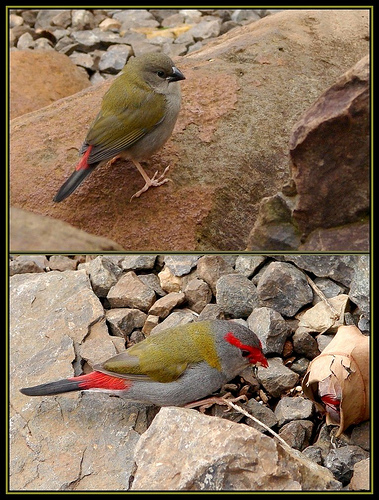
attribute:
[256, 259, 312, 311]
rocks — brown, gray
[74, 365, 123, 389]
feathers — red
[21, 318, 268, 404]
bird — green, feathered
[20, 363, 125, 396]
tail — bird's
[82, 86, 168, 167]
wing — green, feathered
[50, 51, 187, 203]
bird — green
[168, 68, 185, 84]
beak — black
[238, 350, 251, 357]
eye — dark colored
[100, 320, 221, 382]
wing — yellow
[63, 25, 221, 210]
bird — grey, green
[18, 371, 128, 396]
tail — gray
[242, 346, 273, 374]
beak — red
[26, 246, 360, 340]
rock — large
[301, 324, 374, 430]
leaf — dead, tan, rolled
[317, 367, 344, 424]
leaf — old, dry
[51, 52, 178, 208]
bird — green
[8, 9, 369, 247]
rock — orange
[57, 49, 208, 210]
bird — gray, green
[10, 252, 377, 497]
small rocks — brown, grey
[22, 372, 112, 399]
tail — red , black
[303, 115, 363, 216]
stone — large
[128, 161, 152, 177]
leg — yellow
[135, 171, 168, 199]
foot — yellow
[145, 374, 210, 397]
belly — grey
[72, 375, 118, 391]
tail — red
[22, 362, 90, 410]
tail — black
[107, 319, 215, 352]
back — bird's